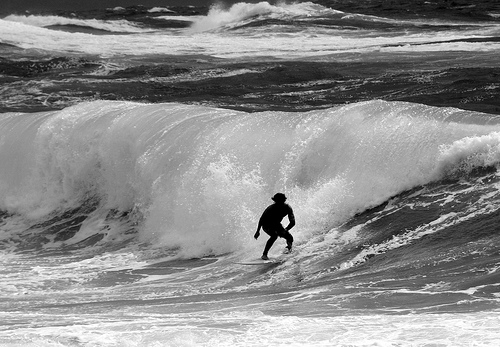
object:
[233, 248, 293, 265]
board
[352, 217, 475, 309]
water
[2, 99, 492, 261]
waters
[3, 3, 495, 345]
ocean water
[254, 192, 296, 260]
man